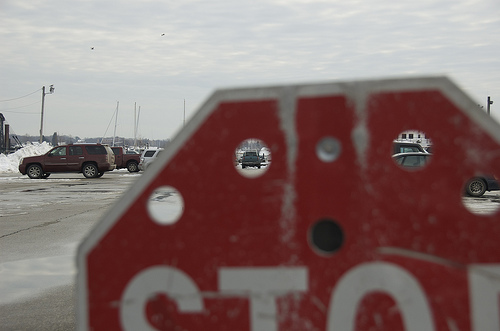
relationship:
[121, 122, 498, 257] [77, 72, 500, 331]
holes in sign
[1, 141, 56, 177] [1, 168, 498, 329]
snow on ground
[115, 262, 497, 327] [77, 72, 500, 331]
lettering on sign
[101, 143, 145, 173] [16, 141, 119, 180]
pick-up next to suv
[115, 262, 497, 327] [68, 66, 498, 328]
lettering on sign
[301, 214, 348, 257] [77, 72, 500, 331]
black circle on sign